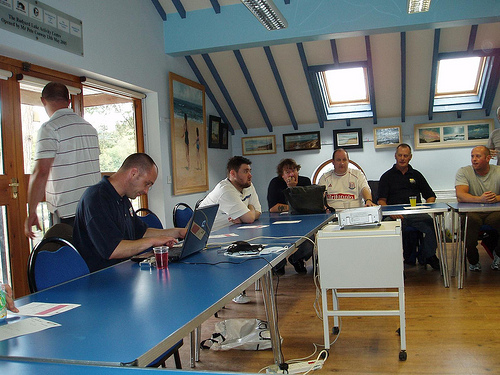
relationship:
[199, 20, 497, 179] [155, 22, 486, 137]
skylights in roof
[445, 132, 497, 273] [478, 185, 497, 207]
man with h hands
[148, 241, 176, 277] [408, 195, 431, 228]
cup with juice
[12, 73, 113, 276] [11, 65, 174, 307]
man looking out door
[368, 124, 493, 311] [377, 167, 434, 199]
man in a shirt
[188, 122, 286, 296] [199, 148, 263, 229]
man with hair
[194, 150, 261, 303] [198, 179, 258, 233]
man in a white shirt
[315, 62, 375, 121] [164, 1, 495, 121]
window in ceiling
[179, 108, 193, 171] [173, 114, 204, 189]
children in beach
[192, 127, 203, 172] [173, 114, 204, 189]
person in beach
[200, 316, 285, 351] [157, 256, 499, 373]
bag on floor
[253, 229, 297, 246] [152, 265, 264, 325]
cord on table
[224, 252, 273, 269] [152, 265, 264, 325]
cord on table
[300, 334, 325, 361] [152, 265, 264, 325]
cord on table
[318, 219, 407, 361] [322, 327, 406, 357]
white stand on wheels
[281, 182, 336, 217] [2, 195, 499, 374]
bag on table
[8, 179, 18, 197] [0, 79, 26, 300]
doorknob on door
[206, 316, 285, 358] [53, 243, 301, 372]
bag under table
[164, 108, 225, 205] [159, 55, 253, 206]
children on beach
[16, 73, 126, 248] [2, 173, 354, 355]
men around tables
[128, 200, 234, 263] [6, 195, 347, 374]
laptop on table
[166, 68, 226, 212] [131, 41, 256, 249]
artwork on wall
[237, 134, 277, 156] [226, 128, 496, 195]
artwork on wall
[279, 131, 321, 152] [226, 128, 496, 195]
artwork on wall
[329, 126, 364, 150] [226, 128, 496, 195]
artwork on wall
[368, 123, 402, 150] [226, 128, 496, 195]
artwork on wall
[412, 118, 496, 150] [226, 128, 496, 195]
artwork on wall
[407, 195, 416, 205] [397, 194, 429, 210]
cup of juice